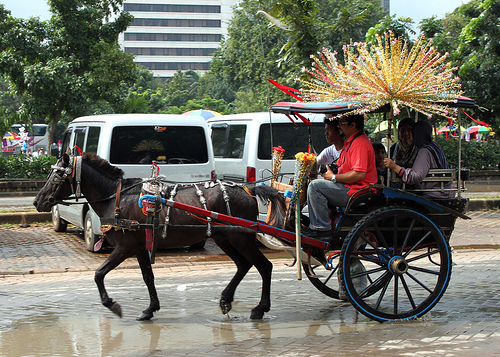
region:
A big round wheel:
[334, 200, 453, 325]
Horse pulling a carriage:
[27, 82, 473, 330]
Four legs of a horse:
[89, 243, 276, 325]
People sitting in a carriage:
[287, 104, 468, 245]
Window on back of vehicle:
[104, 117, 210, 169]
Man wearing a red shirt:
[331, 105, 382, 194]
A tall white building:
[103, 0, 233, 84]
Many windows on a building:
[121, 3, 225, 83]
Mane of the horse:
[80, 144, 128, 187]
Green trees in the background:
[1, 2, 499, 132]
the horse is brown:
[42, 118, 304, 320]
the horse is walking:
[8, 140, 294, 336]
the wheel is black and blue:
[328, 197, 459, 328]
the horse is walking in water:
[29, 262, 298, 335]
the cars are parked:
[20, 75, 419, 268]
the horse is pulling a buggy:
[14, 82, 475, 315]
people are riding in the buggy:
[252, 100, 483, 244]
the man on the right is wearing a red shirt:
[295, 104, 385, 198]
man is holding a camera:
[297, 147, 364, 188]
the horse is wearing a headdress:
[23, 112, 98, 197]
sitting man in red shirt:
[307, 116, 379, 232]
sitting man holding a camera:
[308, 113, 374, 240]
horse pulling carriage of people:
[26, 85, 471, 331]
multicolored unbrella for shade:
[463, 121, 493, 140]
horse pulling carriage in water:
[31, 66, 454, 355]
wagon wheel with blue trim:
[337, 202, 456, 326]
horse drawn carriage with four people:
[30, 35, 470, 322]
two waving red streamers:
[263, 66, 307, 109]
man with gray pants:
[302, 116, 377, 236]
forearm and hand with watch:
[322, 167, 353, 184]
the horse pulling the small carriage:
[33, 147, 473, 324]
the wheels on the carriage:
[301, 206, 453, 325]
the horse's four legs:
[93, 239, 273, 321]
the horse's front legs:
[93, 249, 160, 320]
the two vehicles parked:
[51, 112, 323, 250]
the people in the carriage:
[287, 115, 457, 239]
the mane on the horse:
[80, 149, 122, 179]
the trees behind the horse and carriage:
[0, 0, 497, 175]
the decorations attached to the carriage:
[262, 29, 459, 124]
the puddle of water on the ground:
[2, 276, 441, 356]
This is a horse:
[26, 147, 274, 348]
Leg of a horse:
[133, 248, 166, 322]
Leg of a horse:
[88, 245, 135, 320]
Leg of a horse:
[244, 240, 284, 326]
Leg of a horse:
[212, 246, 249, 319]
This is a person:
[411, 116, 449, 188]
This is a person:
[385, 99, 417, 196]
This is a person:
[339, 103, 379, 185]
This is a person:
[310, 99, 346, 189]